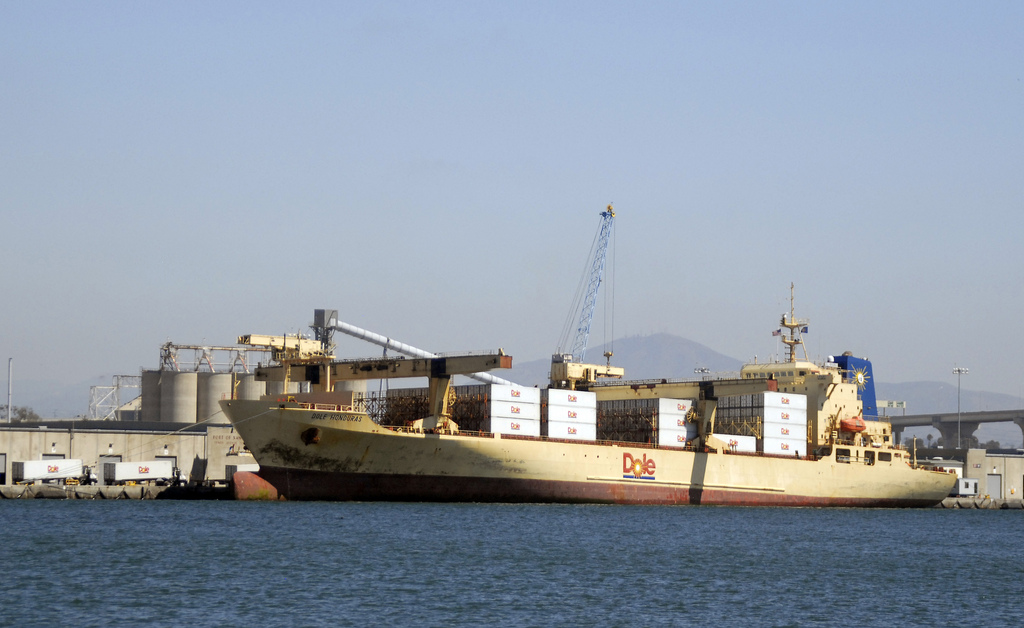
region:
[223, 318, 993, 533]
large tan and brown boat carrying cargo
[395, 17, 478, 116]
white clouds in blue sky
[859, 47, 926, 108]
white clouds in blue sky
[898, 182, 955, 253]
white clouds in blue sky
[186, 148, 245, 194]
white clouds in blue sky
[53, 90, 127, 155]
white clouds in blue sky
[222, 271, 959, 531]
tan and brown boat with cargo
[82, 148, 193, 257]
white clouds in blue sky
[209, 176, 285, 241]
white clouds in blue sky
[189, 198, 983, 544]
tan boat in blue water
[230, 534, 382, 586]
ripples in blue water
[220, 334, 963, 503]
A large ship in the water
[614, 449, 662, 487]
A red logo on a ship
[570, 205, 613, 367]
A metal crane beside a ship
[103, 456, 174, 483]
A white cargo container on a dock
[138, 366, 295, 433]
Concrete tanks near a dock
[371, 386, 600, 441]
Storage containers on a ship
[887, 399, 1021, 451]
A bridge behind a ship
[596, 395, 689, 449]
Storage containers on a ship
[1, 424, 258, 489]
A low building near the water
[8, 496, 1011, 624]
Water with ripples in it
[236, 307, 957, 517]
ship on the water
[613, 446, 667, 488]
dole logo on the ship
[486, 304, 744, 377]
mountain behind the ship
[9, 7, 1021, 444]
clear blue sky above the water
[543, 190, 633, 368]
crane behind the ship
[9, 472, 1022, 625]
dark water the ship is on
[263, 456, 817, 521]
brown bottom on the ship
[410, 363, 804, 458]
containers on the ship's deck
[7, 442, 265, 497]
pier beside the ship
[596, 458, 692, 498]
boat has logo on it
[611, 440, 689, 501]
logo has red text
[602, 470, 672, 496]
logo has blue underline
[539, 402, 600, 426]
A container on a shit.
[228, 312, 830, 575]
a boat on the water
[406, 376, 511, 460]
a container on the boat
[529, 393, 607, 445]
a container on the boat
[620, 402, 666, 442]
a container on the boat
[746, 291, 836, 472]
a container on the boat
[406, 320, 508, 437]
a container on the boat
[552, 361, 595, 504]
a container on the boat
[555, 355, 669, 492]
a container on the boat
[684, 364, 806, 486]
a container on the boat